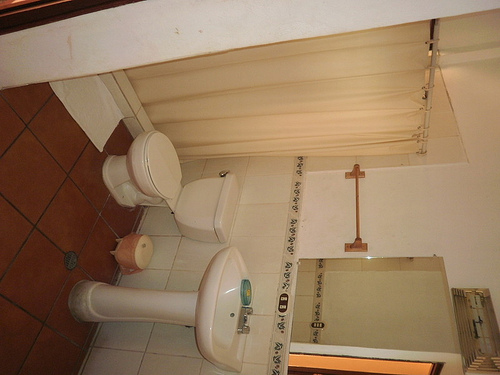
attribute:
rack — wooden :
[341, 164, 371, 254]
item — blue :
[241, 275, 254, 303]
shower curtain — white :
[115, 14, 445, 162]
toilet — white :
[109, 127, 237, 242]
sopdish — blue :
[238, 280, 254, 309]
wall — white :
[108, 66, 493, 161]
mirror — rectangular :
[289, 254, 466, 351]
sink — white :
[74, 241, 259, 374]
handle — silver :
[217, 168, 230, 178]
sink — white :
[62, 243, 260, 370]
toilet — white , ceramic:
[104, 125, 244, 240]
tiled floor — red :
[8, 80, 149, 372]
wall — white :
[2, 2, 496, 96]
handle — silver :
[235, 324, 255, 336]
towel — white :
[36, 70, 128, 157]